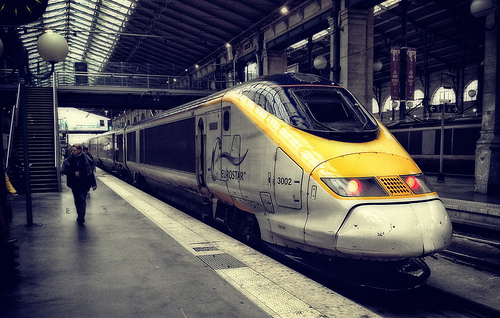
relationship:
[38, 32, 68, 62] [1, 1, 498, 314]
light of station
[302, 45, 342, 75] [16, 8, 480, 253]
light on station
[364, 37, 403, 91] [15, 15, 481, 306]
light of station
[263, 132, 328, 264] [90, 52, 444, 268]
door of train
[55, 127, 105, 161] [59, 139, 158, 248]
head of person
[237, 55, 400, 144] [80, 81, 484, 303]
windshield of train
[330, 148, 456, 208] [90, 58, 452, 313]
headlight of train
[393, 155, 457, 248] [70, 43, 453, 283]
headlight of train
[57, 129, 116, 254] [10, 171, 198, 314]
person on platform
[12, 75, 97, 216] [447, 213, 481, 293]
stairway near tracks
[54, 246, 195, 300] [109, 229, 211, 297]
part of platform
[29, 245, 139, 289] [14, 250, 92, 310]
part of platform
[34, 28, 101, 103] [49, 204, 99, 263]
light of platform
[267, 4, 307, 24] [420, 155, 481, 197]
light above platform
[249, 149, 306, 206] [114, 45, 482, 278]
number on train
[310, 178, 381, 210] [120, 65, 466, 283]
headlight on train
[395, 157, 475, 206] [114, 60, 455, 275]
headlight on train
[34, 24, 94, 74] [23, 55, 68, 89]
lamp on pole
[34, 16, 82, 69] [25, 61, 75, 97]
lamp on pole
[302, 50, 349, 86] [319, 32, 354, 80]
lamp on pole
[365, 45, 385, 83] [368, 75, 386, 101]
lamp on pole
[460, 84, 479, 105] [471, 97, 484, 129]
lamp on pole